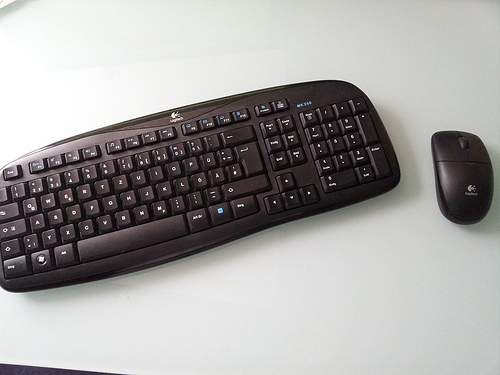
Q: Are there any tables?
A: Yes, there is a table.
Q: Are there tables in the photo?
A: Yes, there is a table.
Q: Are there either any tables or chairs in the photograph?
A: Yes, there is a table.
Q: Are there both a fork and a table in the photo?
A: No, there is a table but no forks.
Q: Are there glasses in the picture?
A: No, there are no glasses.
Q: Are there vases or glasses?
A: No, there are no glasses or vases.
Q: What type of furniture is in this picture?
A: The furniture is a table.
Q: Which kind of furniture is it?
A: The piece of furniture is a table.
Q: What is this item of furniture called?
A: That is a table.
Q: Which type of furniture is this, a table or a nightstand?
A: That is a table.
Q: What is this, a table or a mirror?
A: This is a table.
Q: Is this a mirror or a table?
A: This is a table.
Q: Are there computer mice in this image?
A: Yes, there is a computer mouse.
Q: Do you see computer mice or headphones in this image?
A: Yes, there is a computer mouse.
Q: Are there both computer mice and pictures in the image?
A: No, there is a computer mouse but no pictures.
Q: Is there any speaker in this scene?
A: No, there are no speakers.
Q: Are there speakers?
A: No, there are no speakers.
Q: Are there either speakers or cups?
A: No, there are no speakers or cups.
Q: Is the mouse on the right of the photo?
A: Yes, the mouse is on the right of the image.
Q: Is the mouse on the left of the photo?
A: No, the mouse is on the right of the image.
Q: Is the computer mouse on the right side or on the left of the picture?
A: The computer mouse is on the right of the image.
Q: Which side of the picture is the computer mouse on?
A: The computer mouse is on the right of the image.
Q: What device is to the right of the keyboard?
A: The device is a computer mouse.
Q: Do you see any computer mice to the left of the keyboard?
A: No, the computer mouse is to the right of the keyboard.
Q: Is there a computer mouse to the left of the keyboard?
A: No, the computer mouse is to the right of the keyboard.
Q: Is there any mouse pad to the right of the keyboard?
A: No, there is a computer mouse to the right of the keyboard.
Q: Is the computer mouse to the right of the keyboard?
A: Yes, the computer mouse is to the right of the keyboard.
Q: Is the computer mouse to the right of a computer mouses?
A: No, the computer mouse is to the right of the keyboard.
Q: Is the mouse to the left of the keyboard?
A: No, the mouse is to the right of the keyboard.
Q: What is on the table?
A: The mouse is on the table.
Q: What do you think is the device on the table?
A: The device is a computer mouse.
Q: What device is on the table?
A: The device is a computer mouse.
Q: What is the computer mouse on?
A: The computer mouse is on the table.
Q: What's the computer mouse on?
A: The computer mouse is on the table.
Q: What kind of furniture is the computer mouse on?
A: The computer mouse is on the table.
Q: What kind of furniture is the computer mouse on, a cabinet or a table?
A: The computer mouse is on a table.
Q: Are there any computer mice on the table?
A: Yes, there is a computer mouse on the table.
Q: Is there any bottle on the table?
A: No, there is a computer mouse on the table.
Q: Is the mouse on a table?
A: Yes, the mouse is on a table.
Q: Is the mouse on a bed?
A: No, the mouse is on a table.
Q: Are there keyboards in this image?
A: Yes, there is a keyboard.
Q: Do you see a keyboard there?
A: Yes, there is a keyboard.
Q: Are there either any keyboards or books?
A: Yes, there is a keyboard.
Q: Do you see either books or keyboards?
A: Yes, there is a keyboard.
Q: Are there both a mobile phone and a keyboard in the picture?
A: No, there is a keyboard but no cell phones.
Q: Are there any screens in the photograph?
A: No, there are no screens.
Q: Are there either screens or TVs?
A: No, there are no screens or tvs.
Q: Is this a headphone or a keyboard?
A: This is a keyboard.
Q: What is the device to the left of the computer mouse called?
A: The device is a keyboard.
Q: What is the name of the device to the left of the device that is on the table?
A: The device is a keyboard.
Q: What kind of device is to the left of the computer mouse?
A: The device is a keyboard.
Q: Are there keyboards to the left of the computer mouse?
A: Yes, there is a keyboard to the left of the computer mouse.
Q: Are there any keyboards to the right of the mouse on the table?
A: No, the keyboard is to the left of the computer mouse.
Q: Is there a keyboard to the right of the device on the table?
A: No, the keyboard is to the left of the computer mouse.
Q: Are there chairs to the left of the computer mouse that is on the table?
A: No, there is a keyboard to the left of the computer mouse.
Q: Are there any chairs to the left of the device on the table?
A: No, there is a keyboard to the left of the computer mouse.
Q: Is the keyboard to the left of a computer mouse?
A: Yes, the keyboard is to the left of a computer mouse.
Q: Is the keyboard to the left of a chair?
A: No, the keyboard is to the left of a computer mouse.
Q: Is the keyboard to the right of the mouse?
A: No, the keyboard is to the left of the mouse.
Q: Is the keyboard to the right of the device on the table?
A: No, the keyboard is to the left of the mouse.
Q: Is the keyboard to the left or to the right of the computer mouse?
A: The keyboard is to the left of the computer mouse.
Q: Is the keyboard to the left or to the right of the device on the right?
A: The keyboard is to the left of the computer mouse.